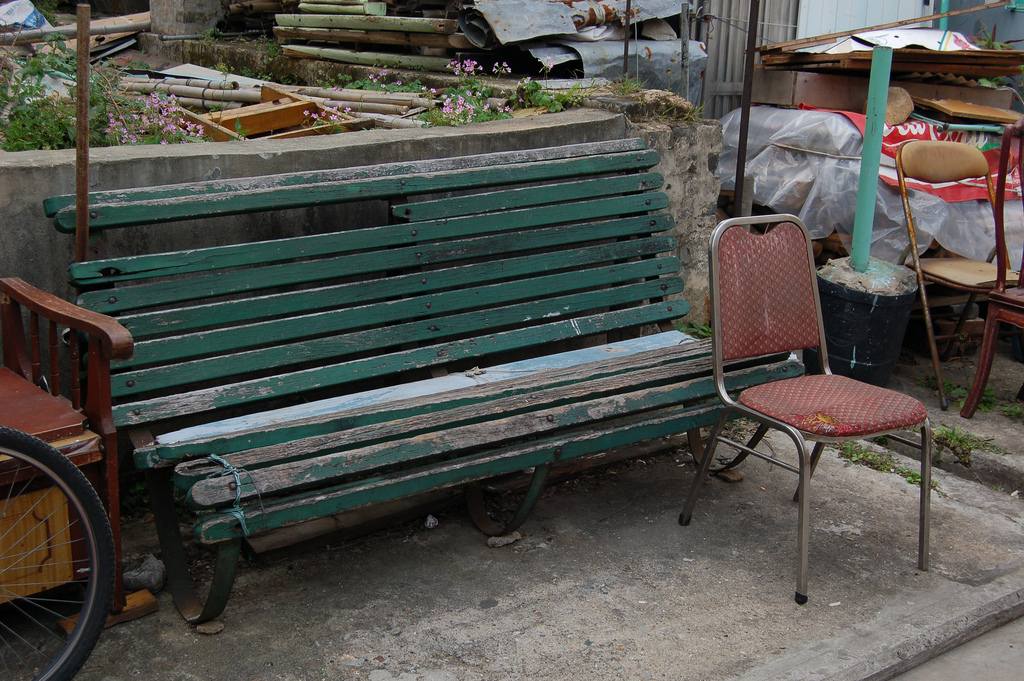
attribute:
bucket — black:
[815, 249, 932, 354]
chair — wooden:
[0, 267, 159, 640]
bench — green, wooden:
[45, 131, 707, 623]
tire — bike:
[6, 417, 127, 677]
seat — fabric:
[734, 363, 929, 439]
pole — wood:
[71, 4, 95, 266]